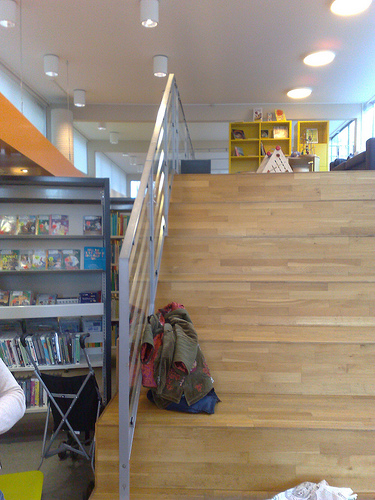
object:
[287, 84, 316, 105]
lights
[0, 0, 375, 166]
ceiling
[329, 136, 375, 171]
couch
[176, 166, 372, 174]
second floor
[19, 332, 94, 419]
stroller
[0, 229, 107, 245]
shelf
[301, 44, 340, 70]
light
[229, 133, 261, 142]
shelf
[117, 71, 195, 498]
balcony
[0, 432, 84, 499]
ground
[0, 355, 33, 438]
arm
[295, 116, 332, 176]
cup board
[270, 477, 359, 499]
paper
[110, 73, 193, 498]
stand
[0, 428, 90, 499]
floor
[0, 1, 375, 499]
scene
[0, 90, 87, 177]
wall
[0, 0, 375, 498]
building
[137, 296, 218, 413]
jacket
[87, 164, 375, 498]
stairs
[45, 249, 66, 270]
book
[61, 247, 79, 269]
book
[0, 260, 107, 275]
shelf